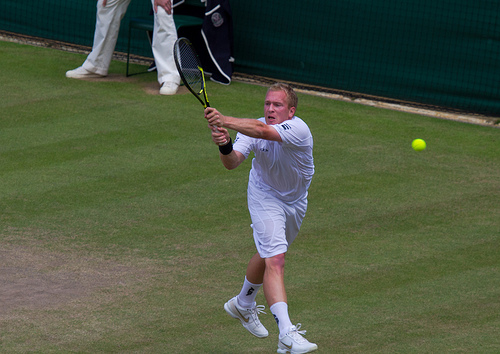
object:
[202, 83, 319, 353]
man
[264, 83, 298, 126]
head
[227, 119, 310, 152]
arm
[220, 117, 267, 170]
arm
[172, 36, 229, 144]
racket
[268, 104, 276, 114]
nose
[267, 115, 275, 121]
mouth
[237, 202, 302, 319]
legs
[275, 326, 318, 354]
shoes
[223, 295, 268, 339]
shoes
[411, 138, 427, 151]
ball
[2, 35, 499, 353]
court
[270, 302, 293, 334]
socks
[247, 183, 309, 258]
shorts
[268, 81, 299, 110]
hair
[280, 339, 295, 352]
logo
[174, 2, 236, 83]
jacket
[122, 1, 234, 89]
chair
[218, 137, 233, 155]
wristband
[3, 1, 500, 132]
fence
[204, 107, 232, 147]
hands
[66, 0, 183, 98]
person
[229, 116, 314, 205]
shirt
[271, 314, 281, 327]
design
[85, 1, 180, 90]
pants